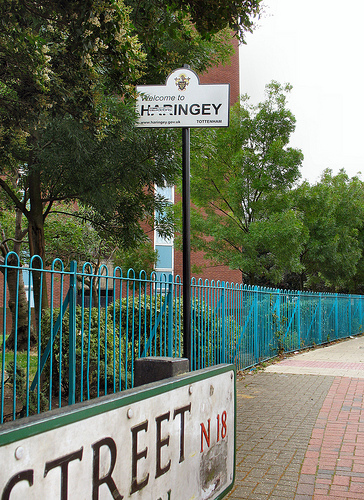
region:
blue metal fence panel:
[26, 257, 47, 393]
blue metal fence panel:
[52, 258, 67, 405]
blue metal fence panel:
[4, 247, 18, 428]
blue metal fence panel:
[100, 262, 107, 399]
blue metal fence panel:
[125, 268, 138, 391]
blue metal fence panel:
[171, 274, 181, 362]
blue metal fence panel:
[189, 275, 200, 375]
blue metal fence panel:
[209, 279, 217, 366]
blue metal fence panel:
[205, 277, 215, 373]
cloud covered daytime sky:
[240, 0, 360, 178]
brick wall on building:
[5, 59, 239, 332]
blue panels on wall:
[150, 243, 172, 290]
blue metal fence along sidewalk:
[1, 252, 361, 417]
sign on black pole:
[138, 62, 230, 358]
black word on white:
[137, 100, 225, 121]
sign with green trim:
[0, 359, 238, 497]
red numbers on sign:
[213, 406, 230, 447]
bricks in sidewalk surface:
[236, 347, 356, 495]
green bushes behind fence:
[64, 293, 341, 378]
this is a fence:
[0, 257, 360, 422]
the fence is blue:
[8, 251, 362, 444]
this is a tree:
[2, 0, 267, 426]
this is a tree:
[0, 209, 99, 361]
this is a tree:
[162, 60, 315, 359]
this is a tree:
[294, 162, 362, 345]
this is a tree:
[47, 308, 135, 407]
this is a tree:
[105, 283, 189, 367]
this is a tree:
[178, 290, 253, 386]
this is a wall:
[0, 358, 242, 496]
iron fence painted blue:
[13, 237, 339, 382]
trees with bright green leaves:
[4, 47, 357, 299]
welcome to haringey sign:
[125, 60, 276, 300]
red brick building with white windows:
[113, 9, 265, 306]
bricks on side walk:
[272, 369, 347, 494]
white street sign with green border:
[62, 382, 273, 496]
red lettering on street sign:
[194, 408, 237, 459]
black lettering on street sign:
[93, 418, 192, 488]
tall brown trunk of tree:
[7, 144, 96, 361]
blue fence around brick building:
[178, 254, 350, 371]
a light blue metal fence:
[3, 247, 360, 429]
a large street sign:
[0, 363, 236, 498]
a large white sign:
[130, 66, 225, 127]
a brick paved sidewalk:
[216, 331, 363, 496]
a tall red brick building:
[1, 7, 240, 306]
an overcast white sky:
[238, 0, 363, 185]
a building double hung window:
[155, 245, 173, 287]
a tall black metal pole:
[180, 126, 193, 357]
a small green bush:
[40, 303, 127, 391]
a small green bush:
[108, 294, 183, 357]